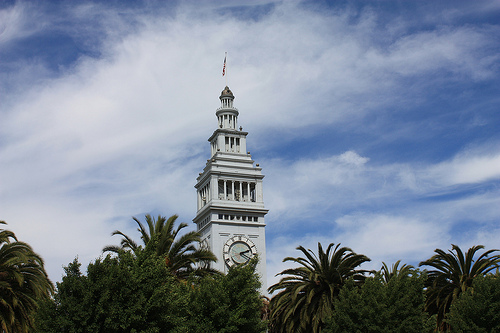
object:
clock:
[197, 237, 212, 277]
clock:
[221, 233, 260, 280]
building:
[190, 79, 280, 329]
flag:
[215, 53, 230, 73]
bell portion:
[189, 175, 264, 208]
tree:
[3, 218, 63, 331]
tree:
[183, 252, 265, 332]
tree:
[101, 212, 221, 298]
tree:
[260, 234, 380, 330]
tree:
[411, 239, 498, 325]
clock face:
[211, 224, 263, 278]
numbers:
[231, 238, 236, 242]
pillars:
[220, 181, 228, 201]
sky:
[317, 115, 447, 241]